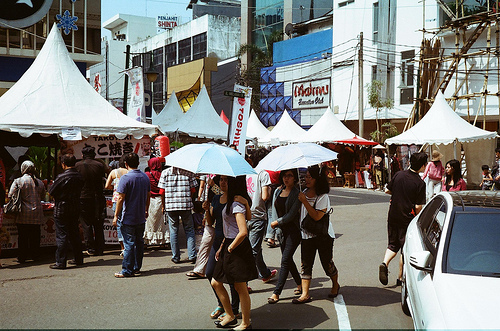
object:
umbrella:
[165, 141, 260, 178]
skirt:
[209, 237, 258, 283]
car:
[401, 190, 500, 331]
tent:
[0, 21, 160, 140]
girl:
[208, 173, 260, 331]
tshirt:
[388, 171, 426, 220]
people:
[110, 152, 149, 278]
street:
[0, 187, 415, 331]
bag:
[300, 195, 333, 236]